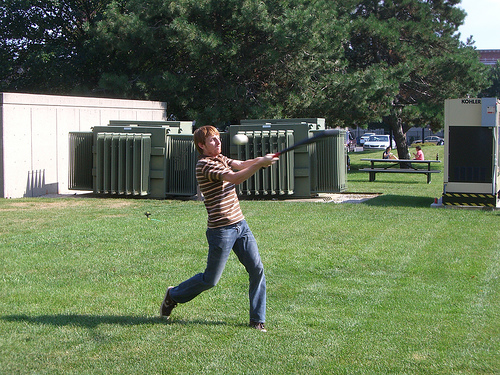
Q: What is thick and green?
A: Trees.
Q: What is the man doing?
A: Hitting a ball.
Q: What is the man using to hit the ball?
A: Bat.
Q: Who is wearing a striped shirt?
A: Man with bat.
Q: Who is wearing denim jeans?
A: Man with stick.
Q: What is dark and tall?
A: Trees.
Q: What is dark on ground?
A: Shadow.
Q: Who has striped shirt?
A: Young man.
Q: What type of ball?
A: Baseball.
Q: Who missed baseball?
A: Young man.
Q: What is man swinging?
A: Baseball bat.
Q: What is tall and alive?
A: Tree.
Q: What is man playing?
A: Baseball.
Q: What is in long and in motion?
A: Bat.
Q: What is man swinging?
A: Bat.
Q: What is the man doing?
A: Swinging bat.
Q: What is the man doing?
A: Hitting a ball.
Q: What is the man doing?
A: Playing baseball ball.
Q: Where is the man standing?
A: In a grass field.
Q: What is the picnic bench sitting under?
A: A large tree.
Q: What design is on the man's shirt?
A: Stripes.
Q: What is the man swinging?
A: Bat.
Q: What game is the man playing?
A: Baseball.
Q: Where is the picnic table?
A: Behind the equipment.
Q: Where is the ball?
A: In the air.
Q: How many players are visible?
A: 1.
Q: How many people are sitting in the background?
A: 2.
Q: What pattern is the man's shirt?
A: Stripes.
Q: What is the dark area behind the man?
A: Shadow.